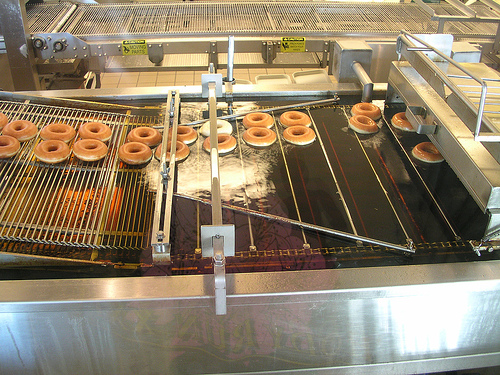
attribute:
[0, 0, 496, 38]
racks — empty, metal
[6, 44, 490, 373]
equipment — metal, industrial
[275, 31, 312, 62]
sign — yellow, black